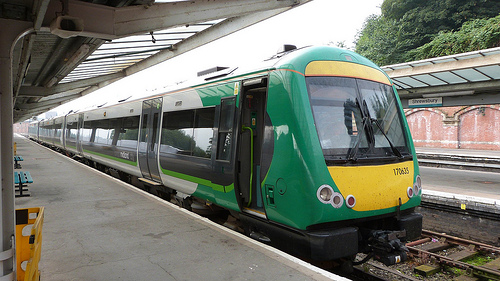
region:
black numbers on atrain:
[366, 159, 416, 191]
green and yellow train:
[282, 50, 423, 232]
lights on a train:
[303, 184, 462, 216]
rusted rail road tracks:
[366, 222, 486, 277]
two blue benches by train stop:
[4, 147, 31, 210]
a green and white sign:
[357, 94, 454, 138]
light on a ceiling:
[25, 41, 109, 122]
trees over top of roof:
[295, 27, 488, 91]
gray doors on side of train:
[100, 90, 182, 255]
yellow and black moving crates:
[10, 196, 92, 274]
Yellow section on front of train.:
[335, 162, 470, 218]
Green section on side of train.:
[273, 90, 343, 252]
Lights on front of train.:
[303, 175, 455, 214]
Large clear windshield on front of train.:
[313, 77, 420, 174]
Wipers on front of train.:
[339, 102, 399, 164]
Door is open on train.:
[218, 154, 325, 227]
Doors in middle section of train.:
[127, 125, 200, 195]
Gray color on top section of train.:
[86, 91, 195, 123]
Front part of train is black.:
[318, 222, 443, 257]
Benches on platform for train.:
[12, 145, 43, 203]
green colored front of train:
[279, 117, 324, 227]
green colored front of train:
[251, 80, 325, 222]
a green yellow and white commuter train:
[72, 45, 428, 264]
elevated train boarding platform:
[10, 132, 342, 279]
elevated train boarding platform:
[407, 141, 497, 162]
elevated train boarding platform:
[410, 160, 499, 217]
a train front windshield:
[302, 70, 409, 168]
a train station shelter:
[0, 1, 311, 278]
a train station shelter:
[370, 54, 499, 151]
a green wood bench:
[10, 167, 32, 199]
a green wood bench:
[11, 154, 22, 166]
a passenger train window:
[160, 107, 212, 159]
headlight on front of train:
[343, 193, 360, 211]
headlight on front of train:
[333, 195, 344, 215]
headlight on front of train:
[318, 182, 330, 209]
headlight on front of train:
[399, 185, 416, 200]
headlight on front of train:
[412, 185, 419, 197]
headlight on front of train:
[412, 174, 425, 185]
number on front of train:
[382, 165, 409, 180]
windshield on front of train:
[295, 68, 414, 165]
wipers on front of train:
[336, 100, 405, 157]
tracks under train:
[405, 226, 480, 278]